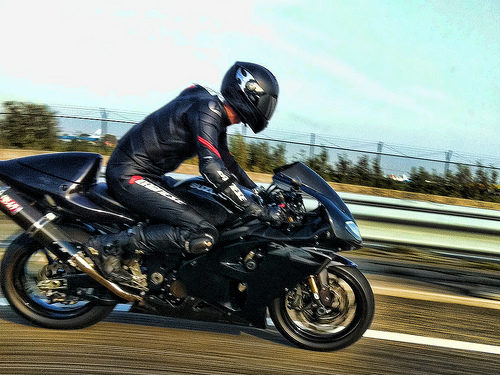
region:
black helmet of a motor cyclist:
[222, 58, 281, 133]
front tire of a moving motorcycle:
[267, 244, 374, 351]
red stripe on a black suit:
[195, 133, 223, 159]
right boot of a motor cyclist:
[83, 226, 151, 296]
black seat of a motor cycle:
[91, 176, 183, 221]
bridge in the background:
[286, 129, 498, 184]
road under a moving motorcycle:
[3, 321, 488, 373]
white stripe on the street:
[373, 320, 497, 353]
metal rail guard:
[368, 194, 498, 261]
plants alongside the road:
[1, 101, 64, 152]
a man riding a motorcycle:
[0, 58, 383, 358]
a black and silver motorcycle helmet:
[214, 52, 285, 144]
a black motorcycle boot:
[86, 214, 183, 289]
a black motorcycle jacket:
[111, 73, 256, 209]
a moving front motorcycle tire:
[267, 248, 380, 356]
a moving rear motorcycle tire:
[0, 225, 118, 332]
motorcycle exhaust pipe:
[0, 176, 145, 311]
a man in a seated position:
[85, 54, 294, 288]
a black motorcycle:
[0, 144, 380, 354]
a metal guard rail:
[324, 180, 499, 264]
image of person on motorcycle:
[3, 42, 411, 362]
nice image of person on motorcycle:
[11, 40, 404, 354]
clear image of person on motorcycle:
[18, 28, 402, 353]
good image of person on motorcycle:
[9, 31, 401, 363]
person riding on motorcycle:
[16, 22, 410, 357]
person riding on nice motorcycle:
[10, 41, 393, 356]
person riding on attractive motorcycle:
[7, 47, 394, 354]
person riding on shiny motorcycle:
[10, 28, 397, 363]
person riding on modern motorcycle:
[21, 41, 401, 359]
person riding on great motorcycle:
[12, 36, 397, 358]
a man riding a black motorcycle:
[0, 61, 375, 374]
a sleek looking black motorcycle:
[1, 152, 374, 372]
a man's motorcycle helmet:
[219, 62, 278, 133]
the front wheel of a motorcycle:
[268, 253, 371, 350]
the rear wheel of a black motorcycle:
[0, 226, 117, 330]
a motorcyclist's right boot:
[82, 232, 144, 293]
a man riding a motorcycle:
[80, 62, 287, 291]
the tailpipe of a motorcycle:
[0, 181, 140, 298]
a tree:
[1, 101, 62, 150]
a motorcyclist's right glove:
[218, 171, 290, 229]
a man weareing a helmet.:
[207, 58, 282, 155]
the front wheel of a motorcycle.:
[263, 242, 375, 362]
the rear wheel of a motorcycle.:
[0, 208, 133, 338]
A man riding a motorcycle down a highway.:
[81, 86, 296, 292]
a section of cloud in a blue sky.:
[316, 48, 437, 128]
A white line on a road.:
[2, 287, 498, 364]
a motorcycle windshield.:
[263, 151, 363, 260]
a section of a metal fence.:
[0, 106, 499, 202]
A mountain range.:
[43, 106, 498, 198]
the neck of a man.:
[205, 93, 246, 142]